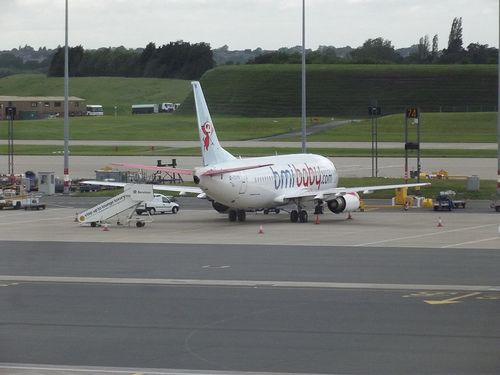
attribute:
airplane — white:
[122, 80, 436, 250]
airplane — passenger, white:
[104, 74, 441, 234]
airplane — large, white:
[80, 86, 407, 263]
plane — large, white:
[106, 77, 433, 225]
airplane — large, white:
[81, 77, 430, 219]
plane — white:
[152, 102, 430, 214]